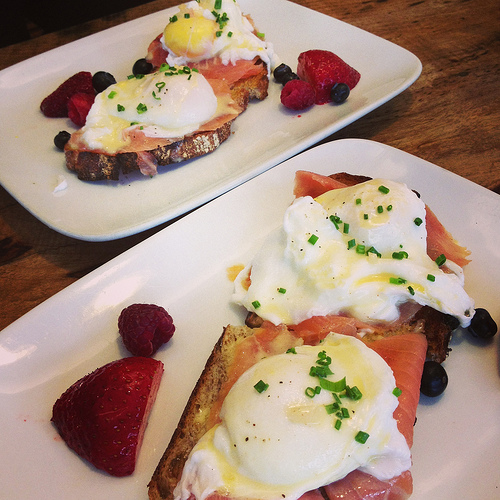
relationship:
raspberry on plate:
[120, 304, 176, 357] [1, 137, 499, 499]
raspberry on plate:
[281, 79, 315, 108] [0, 0, 423, 242]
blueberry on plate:
[329, 83, 350, 104] [0, 0, 423, 242]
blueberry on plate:
[421, 361, 449, 397] [1, 137, 499, 499]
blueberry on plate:
[91, 72, 117, 93] [0, 0, 423, 242]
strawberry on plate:
[53, 355, 164, 478] [1, 137, 499, 499]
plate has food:
[0, 0, 423, 242] [40, 0, 362, 185]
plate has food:
[1, 137, 499, 499] [53, 170, 500, 499]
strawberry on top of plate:
[298, 49, 362, 103] [0, 0, 423, 242]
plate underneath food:
[0, 0, 423, 242] [40, 0, 362, 185]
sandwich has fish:
[149, 170, 474, 498] [210, 317, 430, 499]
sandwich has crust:
[66, 0, 279, 186] [66, 121, 232, 184]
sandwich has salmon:
[66, 0, 279, 186] [148, 11, 266, 87]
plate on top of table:
[0, 0, 423, 242] [0, 1, 500, 332]